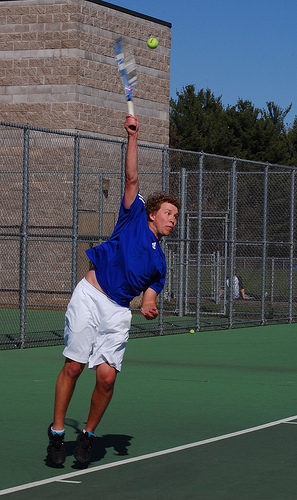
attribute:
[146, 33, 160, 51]
tennis ball — green, airborne, yellow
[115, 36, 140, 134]
racket — blue, white, blue gray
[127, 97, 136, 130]
handle — white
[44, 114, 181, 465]
man — jumping, playing tennis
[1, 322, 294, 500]
court — green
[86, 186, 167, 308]
shirt — blue, short sleeved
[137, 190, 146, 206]
stripes — white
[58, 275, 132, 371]
shorts — white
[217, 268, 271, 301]
man — sitting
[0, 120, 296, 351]
fence — chain link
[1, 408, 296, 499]
line — white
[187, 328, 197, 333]
tennis ball — yellow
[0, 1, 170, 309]
building — gray, tan, tall, stone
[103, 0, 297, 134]
sky — blue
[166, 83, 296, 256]
trees — green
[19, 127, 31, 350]
pole — metal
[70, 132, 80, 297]
pole — metal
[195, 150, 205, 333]
pole — metal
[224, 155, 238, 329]
pole — metal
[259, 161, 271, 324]
pole — metal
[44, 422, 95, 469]
shoes — black, high top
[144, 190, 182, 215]
hair — curly, brown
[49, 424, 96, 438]
socks — blue, white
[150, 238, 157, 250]
logo — white